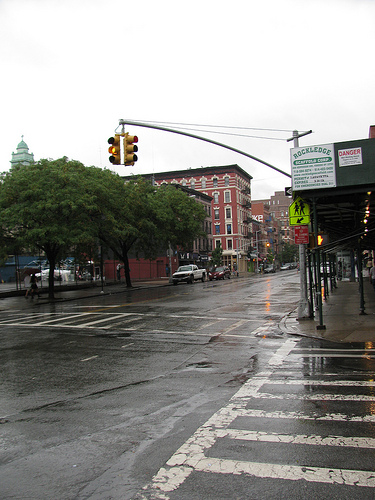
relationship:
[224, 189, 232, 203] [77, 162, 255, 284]
frame on building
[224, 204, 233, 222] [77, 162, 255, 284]
frame on building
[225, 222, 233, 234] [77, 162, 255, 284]
frame on building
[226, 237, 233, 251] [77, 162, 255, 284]
frame on building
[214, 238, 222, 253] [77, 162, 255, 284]
frame on building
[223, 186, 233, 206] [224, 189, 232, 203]
frame around frame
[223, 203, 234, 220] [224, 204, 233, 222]
frame around frame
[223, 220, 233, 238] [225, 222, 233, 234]
frame around frame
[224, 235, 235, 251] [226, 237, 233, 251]
frame around frame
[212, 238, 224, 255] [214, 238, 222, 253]
frame around frame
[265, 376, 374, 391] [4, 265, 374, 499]
line on street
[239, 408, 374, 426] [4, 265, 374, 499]
line on street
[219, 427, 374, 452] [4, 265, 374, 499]
line on street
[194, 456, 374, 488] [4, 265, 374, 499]
line on street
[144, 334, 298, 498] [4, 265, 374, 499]
line on street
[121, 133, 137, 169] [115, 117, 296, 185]
traffic light fixed to post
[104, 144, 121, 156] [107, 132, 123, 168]
light in street light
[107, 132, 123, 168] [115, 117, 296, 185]
traffic light fixed to post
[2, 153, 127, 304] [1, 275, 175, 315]
tree on sidewalk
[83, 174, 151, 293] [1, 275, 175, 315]
tree on sidewalk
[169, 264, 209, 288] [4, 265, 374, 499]
truck at side of street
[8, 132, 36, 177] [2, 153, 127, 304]
tower behind tree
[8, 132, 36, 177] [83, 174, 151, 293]
tower behind tree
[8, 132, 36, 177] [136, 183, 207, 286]
tower behind tree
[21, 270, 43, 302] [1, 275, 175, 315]
couple are on sidewalk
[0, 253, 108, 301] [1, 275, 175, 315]
fence next to sidewalk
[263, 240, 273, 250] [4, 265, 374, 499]
light reflected in street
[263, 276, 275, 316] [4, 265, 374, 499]
reflection in street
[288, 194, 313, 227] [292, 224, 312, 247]
sign on top of traffic sign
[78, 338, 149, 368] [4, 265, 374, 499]
lines are on street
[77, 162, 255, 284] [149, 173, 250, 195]
building has decoration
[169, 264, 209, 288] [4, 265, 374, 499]
truck on side of street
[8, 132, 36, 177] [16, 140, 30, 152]
tower has dome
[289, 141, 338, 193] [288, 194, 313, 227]
sign on top of sign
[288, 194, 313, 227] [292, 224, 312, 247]
sign on top of sign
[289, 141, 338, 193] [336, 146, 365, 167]
sign next to sign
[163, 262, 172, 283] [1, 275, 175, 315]
person on sidewalk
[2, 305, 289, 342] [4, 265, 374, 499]
crosswalk on street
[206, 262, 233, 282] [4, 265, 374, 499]
car on side of street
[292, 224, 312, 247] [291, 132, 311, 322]
traffic sign on pole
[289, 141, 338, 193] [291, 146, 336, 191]
sign has lettering